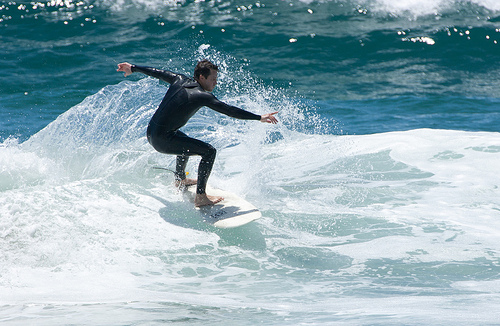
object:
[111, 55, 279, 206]
man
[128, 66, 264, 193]
wet suit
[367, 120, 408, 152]
water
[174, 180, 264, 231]
board